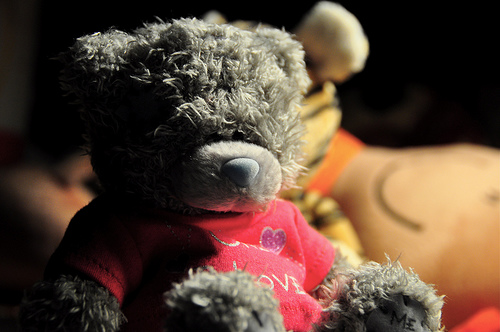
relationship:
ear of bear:
[259, 26, 313, 95] [18, 12, 449, 331]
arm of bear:
[280, 209, 360, 310] [18, 12, 449, 331]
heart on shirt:
[257, 225, 290, 257] [49, 183, 344, 330]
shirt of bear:
[49, 183, 344, 330] [18, 12, 449, 331]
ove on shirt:
[253, 267, 307, 301] [49, 183, 344, 330]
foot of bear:
[313, 252, 446, 330] [18, 12, 449, 331]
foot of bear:
[156, 260, 291, 331] [18, 12, 449, 331]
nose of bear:
[218, 152, 261, 186] [18, 12, 449, 331]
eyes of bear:
[257, 84, 276, 110] [18, 12, 449, 331]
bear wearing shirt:
[18, 12, 449, 331] [49, 183, 344, 330]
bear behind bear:
[18, 12, 449, 331] [18, 12, 449, 331]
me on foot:
[387, 308, 416, 331] [313, 252, 446, 330]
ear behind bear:
[293, 1, 373, 84] [18, 12, 449, 331]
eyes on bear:
[257, 84, 276, 110] [18, 12, 449, 331]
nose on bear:
[218, 152, 261, 186] [18, 12, 449, 331]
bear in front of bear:
[18, 12, 449, 331] [18, 12, 449, 331]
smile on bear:
[369, 157, 423, 234] [18, 12, 449, 331]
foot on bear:
[313, 252, 446, 330] [18, 12, 449, 331]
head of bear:
[54, 10, 316, 222] [18, 12, 449, 331]